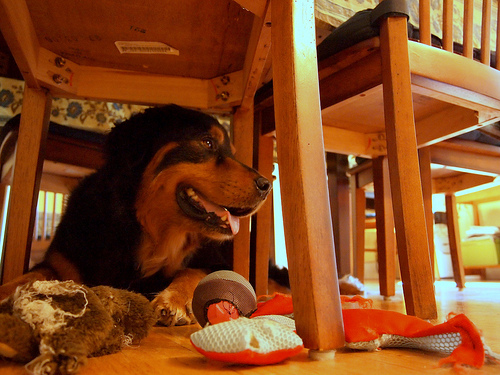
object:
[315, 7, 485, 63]
cushion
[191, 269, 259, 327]
ball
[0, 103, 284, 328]
dog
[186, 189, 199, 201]
teeth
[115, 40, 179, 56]
label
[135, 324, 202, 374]
floor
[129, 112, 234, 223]
face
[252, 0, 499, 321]
chair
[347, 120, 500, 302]
chair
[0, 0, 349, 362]
chair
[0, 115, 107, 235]
chair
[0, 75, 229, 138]
table cloth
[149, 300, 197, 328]
claws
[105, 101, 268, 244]
head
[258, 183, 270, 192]
nostril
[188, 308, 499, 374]
toy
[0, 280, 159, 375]
toy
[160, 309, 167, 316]
nails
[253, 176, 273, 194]
nose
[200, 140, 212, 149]
eye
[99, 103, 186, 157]
ear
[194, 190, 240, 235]
tongue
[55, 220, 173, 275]
fur